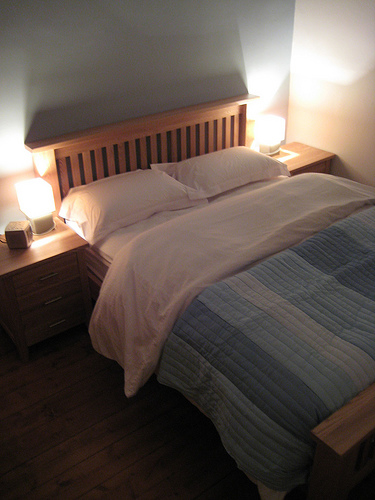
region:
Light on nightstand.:
[13, 171, 70, 241]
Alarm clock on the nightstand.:
[7, 216, 43, 267]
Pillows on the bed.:
[62, 172, 371, 274]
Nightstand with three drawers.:
[7, 193, 108, 343]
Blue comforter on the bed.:
[195, 265, 354, 342]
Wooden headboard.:
[33, 100, 333, 160]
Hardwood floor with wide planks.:
[50, 375, 161, 439]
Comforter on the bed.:
[162, 190, 337, 387]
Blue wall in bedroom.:
[123, 38, 165, 50]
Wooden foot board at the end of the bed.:
[312, 358, 368, 463]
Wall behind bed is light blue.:
[0, 2, 295, 235]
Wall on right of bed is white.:
[285, 0, 373, 190]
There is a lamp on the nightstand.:
[252, 107, 288, 157]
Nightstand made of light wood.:
[251, 138, 336, 182]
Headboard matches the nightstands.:
[16, 87, 264, 222]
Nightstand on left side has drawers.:
[0, 212, 110, 368]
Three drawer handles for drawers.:
[36, 263, 70, 334]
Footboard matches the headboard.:
[290, 381, 373, 498]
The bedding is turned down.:
[87, 169, 374, 458]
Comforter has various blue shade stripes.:
[159, 200, 374, 498]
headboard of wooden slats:
[20, 76, 280, 193]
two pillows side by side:
[61, 126, 301, 242]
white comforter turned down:
[80, 159, 353, 400]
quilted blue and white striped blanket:
[168, 276, 355, 460]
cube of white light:
[11, 166, 56, 234]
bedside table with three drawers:
[5, 195, 88, 352]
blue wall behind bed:
[38, 30, 274, 76]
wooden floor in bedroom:
[53, 396, 182, 487]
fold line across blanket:
[166, 235, 370, 397]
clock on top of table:
[2, 218, 53, 263]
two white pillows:
[59, 145, 315, 238]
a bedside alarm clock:
[4, 219, 35, 250]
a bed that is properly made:
[23, 106, 373, 491]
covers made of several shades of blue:
[139, 207, 371, 478]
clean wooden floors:
[0, 372, 115, 496]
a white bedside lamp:
[251, 112, 286, 157]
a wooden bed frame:
[22, 90, 263, 218]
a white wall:
[0, 3, 286, 79]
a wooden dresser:
[0, 218, 93, 363]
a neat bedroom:
[0, 98, 373, 498]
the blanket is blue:
[206, 278, 319, 418]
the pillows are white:
[73, 146, 304, 227]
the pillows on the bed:
[69, 161, 325, 248]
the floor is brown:
[34, 400, 144, 494]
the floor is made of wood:
[15, 394, 143, 497]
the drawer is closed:
[2, 260, 124, 353]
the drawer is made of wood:
[3, 257, 100, 349]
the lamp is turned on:
[16, 171, 72, 249]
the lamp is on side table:
[2, 180, 97, 290]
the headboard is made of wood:
[24, 116, 312, 201]